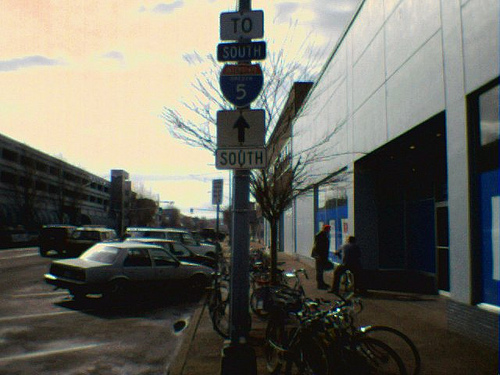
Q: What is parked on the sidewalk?
A: Bikes.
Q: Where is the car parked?
A: By sidewalk.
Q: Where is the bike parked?
A: Near pole.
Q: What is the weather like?
A: Cloudy.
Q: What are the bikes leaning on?
A: Pole.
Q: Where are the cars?
A: Parked.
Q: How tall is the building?
A: The building is short.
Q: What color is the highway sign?
A: Blue and red.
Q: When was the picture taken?
A: Daytime.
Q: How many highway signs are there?
A: One.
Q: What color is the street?
A: Black.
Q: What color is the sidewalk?
A: Gray.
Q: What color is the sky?
A: Gray and white.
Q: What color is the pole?
A: Silver.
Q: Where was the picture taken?
A: On the sidewalk.